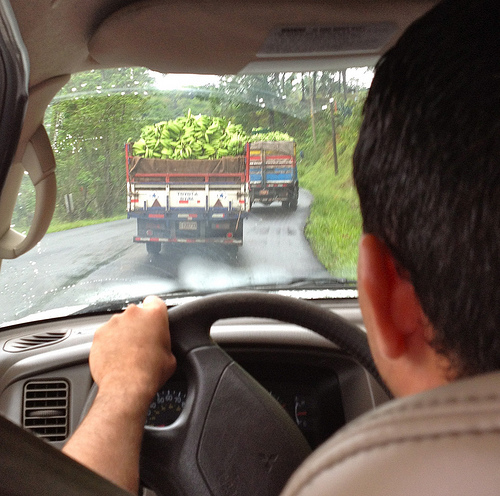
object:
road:
[0, 189, 332, 326]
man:
[60, 1, 499, 494]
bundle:
[169, 121, 180, 137]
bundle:
[203, 144, 217, 157]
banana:
[205, 130, 213, 135]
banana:
[186, 147, 192, 157]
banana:
[206, 151, 215, 156]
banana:
[236, 128, 240, 134]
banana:
[166, 124, 179, 136]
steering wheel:
[83, 288, 396, 494]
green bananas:
[144, 146, 149, 159]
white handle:
[0, 129, 57, 260]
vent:
[21, 374, 72, 443]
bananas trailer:
[204, 132, 211, 144]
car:
[126, 141, 250, 255]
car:
[250, 140, 305, 212]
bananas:
[187, 107, 193, 121]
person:
[62, 9, 500, 496]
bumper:
[132, 233, 244, 246]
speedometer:
[132, 380, 188, 425]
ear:
[354, 229, 418, 365]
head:
[353, 0, 498, 400]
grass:
[298, 148, 364, 280]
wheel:
[145, 240, 161, 254]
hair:
[351, 1, 498, 383]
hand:
[85, 295, 175, 392]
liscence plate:
[179, 222, 198, 231]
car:
[0, 0, 500, 496]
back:
[123, 113, 295, 256]